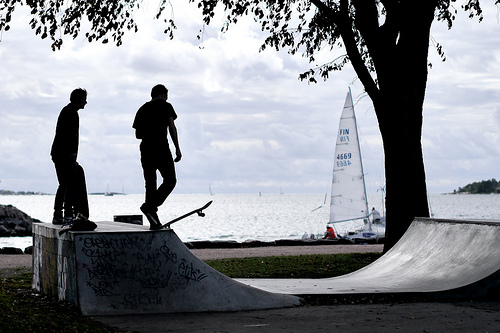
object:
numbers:
[336, 160, 342, 168]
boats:
[257, 189, 266, 199]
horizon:
[125, 187, 438, 198]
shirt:
[130, 98, 177, 143]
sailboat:
[201, 183, 219, 197]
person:
[367, 207, 381, 225]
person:
[322, 224, 340, 242]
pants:
[137, 136, 177, 206]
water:
[1, 192, 500, 245]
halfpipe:
[27, 216, 500, 312]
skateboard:
[157, 198, 214, 232]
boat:
[301, 86, 384, 241]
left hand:
[172, 150, 184, 163]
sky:
[0, 1, 500, 193]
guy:
[49, 86, 98, 234]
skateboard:
[62, 162, 93, 220]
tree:
[187, 0, 485, 258]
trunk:
[365, 4, 433, 257]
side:
[72, 230, 299, 316]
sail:
[327, 86, 368, 222]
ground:
[0, 243, 500, 333]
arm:
[166, 103, 180, 151]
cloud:
[0, 0, 500, 195]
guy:
[131, 85, 179, 230]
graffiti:
[75, 235, 219, 312]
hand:
[73, 158, 79, 164]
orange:
[323, 226, 336, 236]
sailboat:
[367, 187, 386, 222]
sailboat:
[278, 182, 287, 194]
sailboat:
[119, 186, 125, 197]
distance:
[0, 187, 485, 202]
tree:
[452, 189, 456, 193]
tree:
[470, 184, 477, 194]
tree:
[472, 181, 474, 189]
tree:
[463, 186, 469, 192]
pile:
[0, 205, 46, 238]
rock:
[1, 224, 11, 235]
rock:
[16, 226, 26, 236]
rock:
[6, 219, 19, 230]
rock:
[16, 210, 25, 219]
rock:
[30, 217, 42, 225]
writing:
[334, 153, 352, 167]